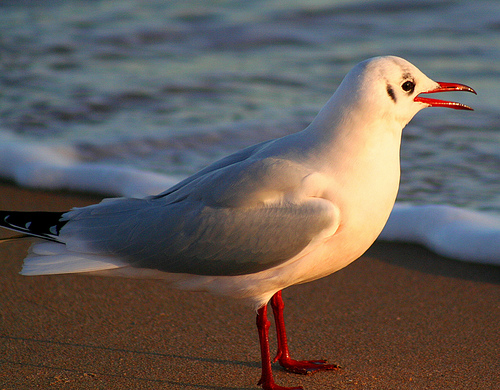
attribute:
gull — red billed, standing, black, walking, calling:
[1, 55, 479, 389]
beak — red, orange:
[413, 81, 477, 114]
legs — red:
[255, 290, 342, 388]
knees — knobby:
[261, 300, 284, 330]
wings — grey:
[64, 154, 327, 277]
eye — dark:
[402, 81, 413, 92]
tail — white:
[20, 243, 121, 277]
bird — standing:
[1, 56, 479, 389]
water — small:
[3, 2, 303, 128]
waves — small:
[1, 93, 306, 136]